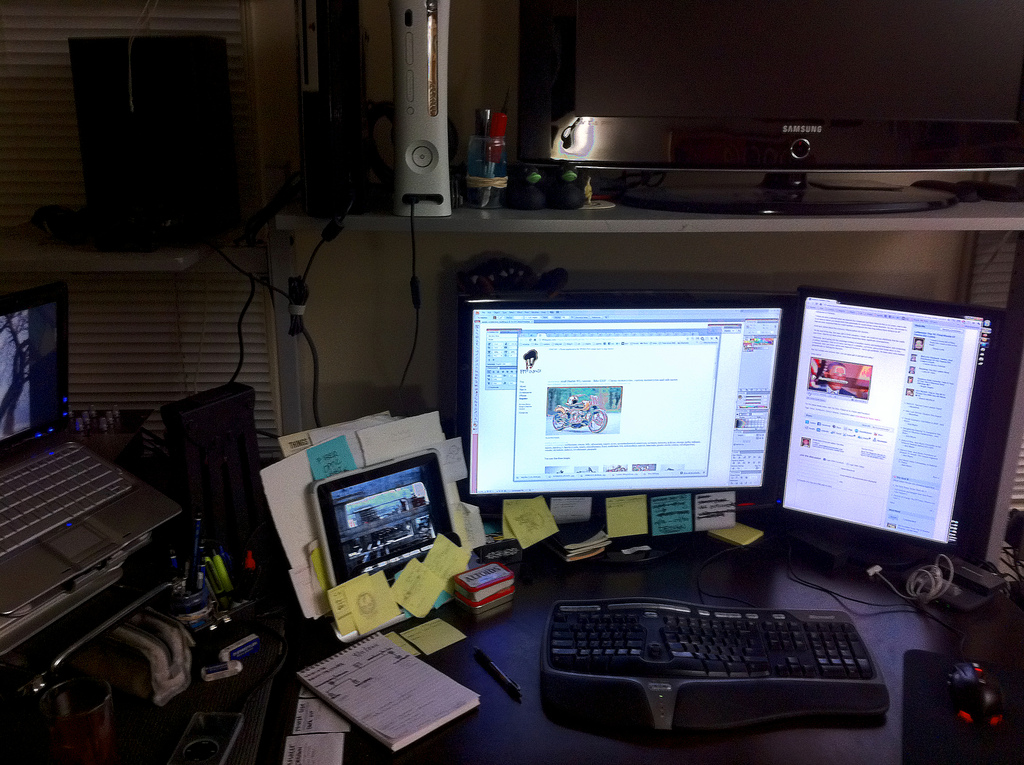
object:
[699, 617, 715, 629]
key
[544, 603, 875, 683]
keyboard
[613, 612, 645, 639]
key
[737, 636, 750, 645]
key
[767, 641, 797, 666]
key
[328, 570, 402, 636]
post-it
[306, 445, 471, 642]
monitor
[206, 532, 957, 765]
table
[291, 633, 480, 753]
notepad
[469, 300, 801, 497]
monitor screen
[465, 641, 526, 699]
pen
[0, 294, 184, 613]
laptop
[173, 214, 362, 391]
cords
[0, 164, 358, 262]
shelf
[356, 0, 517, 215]
shelf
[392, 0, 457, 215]
speaker